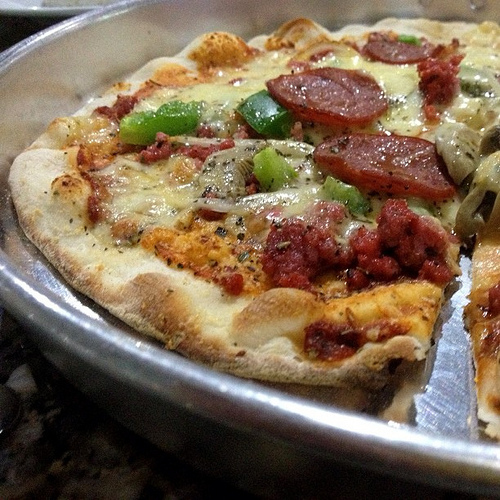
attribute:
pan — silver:
[2, 1, 500, 498]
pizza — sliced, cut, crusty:
[11, 20, 499, 405]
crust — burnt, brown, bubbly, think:
[9, 121, 428, 386]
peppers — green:
[112, 95, 205, 153]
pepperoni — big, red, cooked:
[264, 64, 389, 128]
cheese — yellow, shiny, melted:
[85, 33, 496, 274]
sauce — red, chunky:
[263, 197, 451, 285]